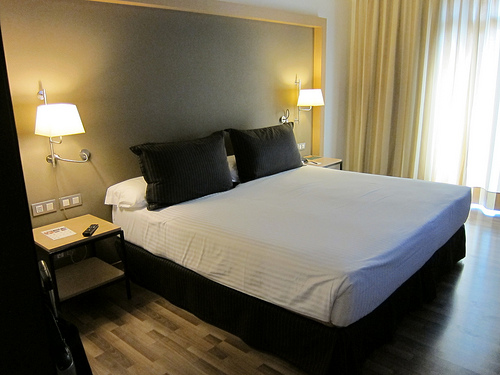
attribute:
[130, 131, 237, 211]
pillow — here, black, upright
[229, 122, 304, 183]
pillow — here, black, upright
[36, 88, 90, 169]
lamp — here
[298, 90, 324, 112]
lamp — here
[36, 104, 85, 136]
light — on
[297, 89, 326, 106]
light — on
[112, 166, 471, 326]
bed cover — white, fresh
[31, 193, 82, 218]
switch — here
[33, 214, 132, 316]
table — wood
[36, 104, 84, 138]
lamp shade — white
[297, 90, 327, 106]
lamp shade — white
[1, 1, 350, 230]
wall — white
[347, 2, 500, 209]
curtain — gold, here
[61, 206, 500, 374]
floor — wood, dark brown, smooth, wooden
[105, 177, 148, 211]
pillow — white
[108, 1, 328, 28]
frame — gold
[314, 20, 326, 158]
frame — gold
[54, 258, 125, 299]
rack — empty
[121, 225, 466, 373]
bed skirt — black